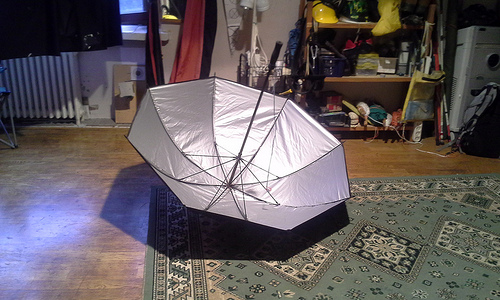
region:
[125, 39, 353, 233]
an upside down umbrella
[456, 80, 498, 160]
a black and white backpack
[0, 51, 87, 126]
white radiator on wall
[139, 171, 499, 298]
a green diamond design rug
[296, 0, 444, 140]
shelf filled with items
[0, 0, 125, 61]
a black window curtain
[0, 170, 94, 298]
light reflection off wooden floor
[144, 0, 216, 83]
red and black curtains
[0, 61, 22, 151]
corner of a blue chair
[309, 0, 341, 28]
a yellow hard hat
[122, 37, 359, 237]
a black and gray umbrella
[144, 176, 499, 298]
a green area rug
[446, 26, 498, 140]
a small white refrigerator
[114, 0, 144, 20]
part of a window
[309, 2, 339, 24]
a yellow helmet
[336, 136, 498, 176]
brown hardwood floor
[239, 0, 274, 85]
part of a white floor lamp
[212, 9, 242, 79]
part of a white wall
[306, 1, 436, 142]
a brown shelf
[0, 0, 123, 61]
a dark curtain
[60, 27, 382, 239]
This is a photography umbrella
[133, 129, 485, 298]
There is a green carpet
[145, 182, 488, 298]
The carpet is on hard wood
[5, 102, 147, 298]
The floor is hardwood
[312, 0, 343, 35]
There is a yellow construction helmet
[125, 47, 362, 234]
The umbrella is upside down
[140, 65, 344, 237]
The umbrella reflects light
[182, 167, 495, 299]
The carpet has a pattern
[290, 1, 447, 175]
There is a wooden shelf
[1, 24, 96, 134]
The radiator is white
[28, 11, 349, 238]
umbrella on the floor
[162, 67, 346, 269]
umbrella on the floor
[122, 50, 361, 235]
A open umbrella.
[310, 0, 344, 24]
A yellow safety helmet.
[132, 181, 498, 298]
A green area rug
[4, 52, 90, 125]
A white wall furnace.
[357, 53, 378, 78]
A stack of plastic boxes.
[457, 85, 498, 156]
A gray and black backpack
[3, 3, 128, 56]
A black curtain covering a window.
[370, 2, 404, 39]
A yellow shopping bag.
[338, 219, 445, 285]
A diamond on a rug.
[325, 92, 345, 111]
A brown and red cardboard box.